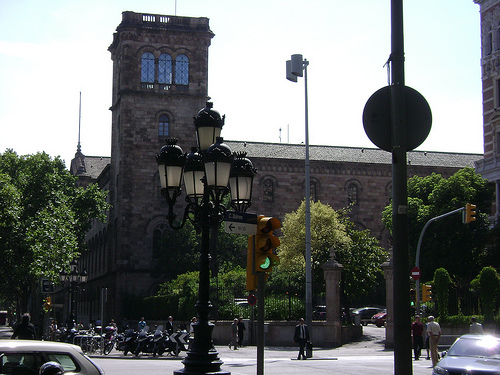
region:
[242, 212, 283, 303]
a yellow stoplight lit green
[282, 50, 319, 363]
a tall light pole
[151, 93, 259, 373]
a decorative light pole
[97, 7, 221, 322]
a building tower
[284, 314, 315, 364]
a man in a black suit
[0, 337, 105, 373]
a parked cream colored car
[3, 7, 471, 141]
a partially clouded sky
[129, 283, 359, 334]
a black iron fence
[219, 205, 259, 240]
a black and white street sign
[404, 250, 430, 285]
a red and white road sign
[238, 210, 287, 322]
Traffic light with a green light lit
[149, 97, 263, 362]
Lamp post on the street corner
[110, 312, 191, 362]
Motorcycles parked on the corner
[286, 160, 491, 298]
Full green growing trees on the sidewalk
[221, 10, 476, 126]
Hazy white sky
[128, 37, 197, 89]
Three large windows in the building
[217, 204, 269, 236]
Street sign with an arrow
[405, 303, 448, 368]
People crossing the street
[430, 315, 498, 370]
Car parked on the street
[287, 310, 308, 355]
Man wearing a suit and tie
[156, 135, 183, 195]
metal casting covered light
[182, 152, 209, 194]
metal casting covered light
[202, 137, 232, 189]
metal casting covered light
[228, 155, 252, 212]
metal casting covered light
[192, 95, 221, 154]
metal casting covered light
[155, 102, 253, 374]
multi-light black metal light post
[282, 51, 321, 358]
multi-light silver metal light post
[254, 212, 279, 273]
yellow metal stop sign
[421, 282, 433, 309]
yellow metal stop sign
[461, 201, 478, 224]
yellow metal stop sign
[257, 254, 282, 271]
green light on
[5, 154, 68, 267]
leaves from trees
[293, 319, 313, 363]
man with suitcase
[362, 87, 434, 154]
a circular object in gray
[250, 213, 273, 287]
three parts of traffic light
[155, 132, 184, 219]
part of light structure on street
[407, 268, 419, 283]
a red and white sign on pole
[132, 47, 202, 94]
windows in brick building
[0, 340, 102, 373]
back part of light-colored car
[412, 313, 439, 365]
two men crossing street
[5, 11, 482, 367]
Outdoor view, taken in spring or summer.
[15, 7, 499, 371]
Attractive street scene, in town setting.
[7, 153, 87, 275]
Tall trees, beside church.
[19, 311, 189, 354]
People traveling, to and from the area beside the church.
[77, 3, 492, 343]
Elderly stone church with towers and fence.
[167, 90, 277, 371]
Short modern traffic light beside old-fashioned street lamp with multiple lights.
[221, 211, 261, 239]
Two-toned sign between light fixtures.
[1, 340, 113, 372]
White car with passengers, turning left, away from church.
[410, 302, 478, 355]
Pedestrians crossing intersection, headed towards church.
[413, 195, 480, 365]
Long, overhanging, tall pole with dual traffic lights and do not enter sign.